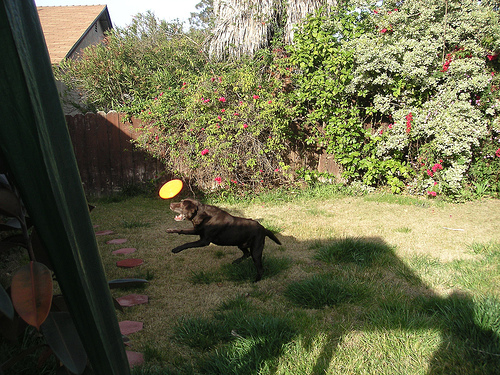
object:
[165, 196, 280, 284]
dog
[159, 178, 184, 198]
frisbee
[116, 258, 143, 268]
stone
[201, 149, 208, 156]
flower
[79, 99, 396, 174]
fence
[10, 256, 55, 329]
leaf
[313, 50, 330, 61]
leaves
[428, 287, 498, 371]
shadow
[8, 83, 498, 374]
back yard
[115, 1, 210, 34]
sky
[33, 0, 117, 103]
house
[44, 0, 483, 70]
background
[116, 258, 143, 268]
frisbee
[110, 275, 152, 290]
stone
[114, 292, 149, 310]
stone